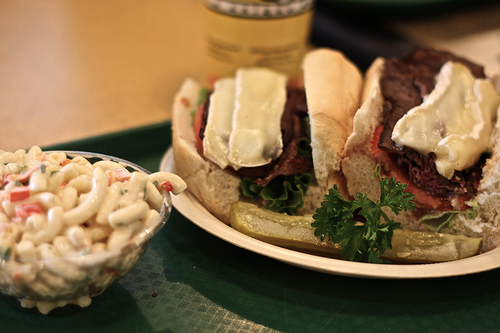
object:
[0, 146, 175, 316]
bowl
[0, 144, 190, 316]
macaroni salad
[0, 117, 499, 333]
tray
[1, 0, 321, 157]
table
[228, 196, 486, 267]
pickle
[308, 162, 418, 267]
parsley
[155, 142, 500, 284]
plate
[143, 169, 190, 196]
macaroni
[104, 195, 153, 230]
macaroni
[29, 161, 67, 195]
macaroni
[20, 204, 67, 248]
macaroni